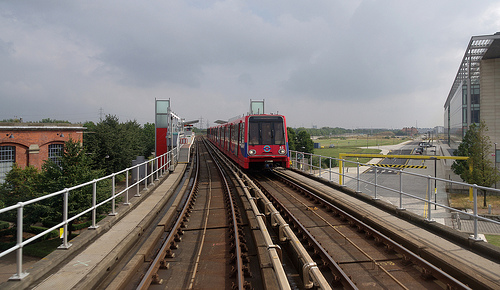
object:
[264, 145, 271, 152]
circle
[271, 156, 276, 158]
spots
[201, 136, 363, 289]
tracks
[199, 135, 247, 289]
tracks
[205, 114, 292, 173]
train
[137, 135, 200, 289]
track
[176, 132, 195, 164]
platform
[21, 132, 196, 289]
trackside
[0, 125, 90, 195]
building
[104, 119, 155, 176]
trees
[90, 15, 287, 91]
clouds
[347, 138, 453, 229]
highway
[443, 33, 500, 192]
building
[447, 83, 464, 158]
glass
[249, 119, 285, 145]
windshield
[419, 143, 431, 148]
cars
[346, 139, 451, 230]
street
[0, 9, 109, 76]
clouds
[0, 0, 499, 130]
sky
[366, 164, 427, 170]
post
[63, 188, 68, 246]
post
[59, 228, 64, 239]
sign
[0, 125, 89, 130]
roof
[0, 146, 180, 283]
railing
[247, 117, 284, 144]
window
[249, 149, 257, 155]
lights